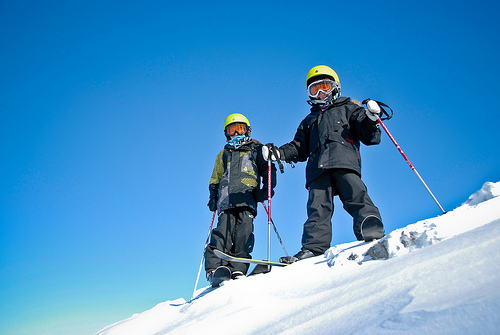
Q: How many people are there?
A: 2.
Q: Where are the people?
A: Mountain.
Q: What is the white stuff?
A: Snow.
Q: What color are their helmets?
A: Yellow.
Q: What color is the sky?
A: Blue.